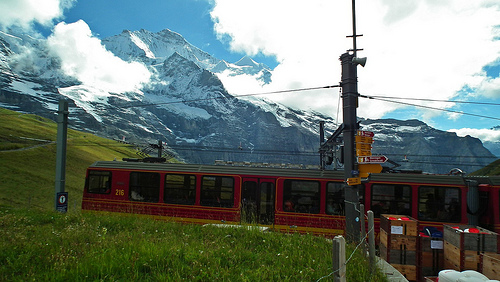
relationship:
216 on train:
[116, 181, 142, 205] [87, 145, 486, 266]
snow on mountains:
[20, 52, 232, 127] [20, 11, 495, 182]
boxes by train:
[370, 194, 492, 281] [87, 145, 486, 266]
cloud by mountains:
[206, 0, 498, 99] [20, 11, 495, 182]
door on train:
[240, 168, 282, 218] [87, 145, 486, 266]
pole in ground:
[332, 39, 403, 250] [10, 155, 433, 282]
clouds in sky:
[33, 14, 160, 77] [35, 5, 483, 90]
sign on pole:
[356, 144, 402, 172] [332, 39, 403, 250]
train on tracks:
[87, 145, 486, 266] [90, 177, 490, 280]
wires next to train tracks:
[90, 76, 337, 120] [18, 13, 485, 277]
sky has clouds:
[18, 5, 494, 179] [33, 14, 160, 77]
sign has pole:
[355, 145, 398, 176] [332, 39, 403, 250]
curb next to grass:
[354, 235, 423, 280] [16, 207, 263, 278]